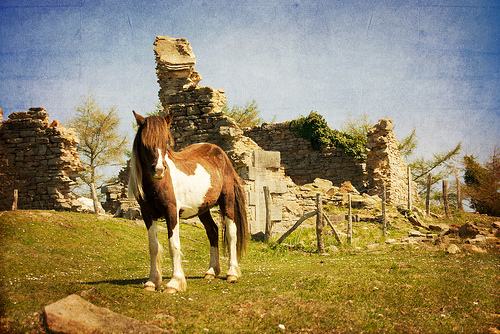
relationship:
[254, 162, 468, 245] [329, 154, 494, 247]
fence surrounds rock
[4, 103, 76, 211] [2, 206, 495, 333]
rock wall crumbling on field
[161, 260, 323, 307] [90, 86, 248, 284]
grass surrounds pony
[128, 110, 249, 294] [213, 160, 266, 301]
animal has tail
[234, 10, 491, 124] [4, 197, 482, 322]
sky hovering above field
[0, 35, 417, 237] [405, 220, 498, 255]
building displayed next to fence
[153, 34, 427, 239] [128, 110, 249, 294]
building behind animal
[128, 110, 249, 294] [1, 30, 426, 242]
animal in front of rock wall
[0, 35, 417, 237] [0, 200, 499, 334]
building rolling on field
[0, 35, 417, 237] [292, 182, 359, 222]
building made of rock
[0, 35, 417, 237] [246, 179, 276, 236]
building made of wood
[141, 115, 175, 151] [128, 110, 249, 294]
hair on animal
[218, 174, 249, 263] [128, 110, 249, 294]
tail on animal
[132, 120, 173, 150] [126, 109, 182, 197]
hair obstructing face